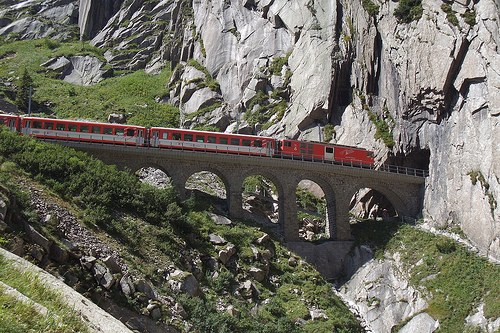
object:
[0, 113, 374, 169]
train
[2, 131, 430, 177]
tracks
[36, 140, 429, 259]
bridge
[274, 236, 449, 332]
gully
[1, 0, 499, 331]
grass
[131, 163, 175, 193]
arch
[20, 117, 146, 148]
car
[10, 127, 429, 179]
railing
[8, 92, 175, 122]
bushes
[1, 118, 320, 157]
windows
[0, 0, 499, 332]
rocks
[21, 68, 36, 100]
tree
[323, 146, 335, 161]
door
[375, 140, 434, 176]
tunnel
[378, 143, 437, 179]
entrance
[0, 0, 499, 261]
mountain